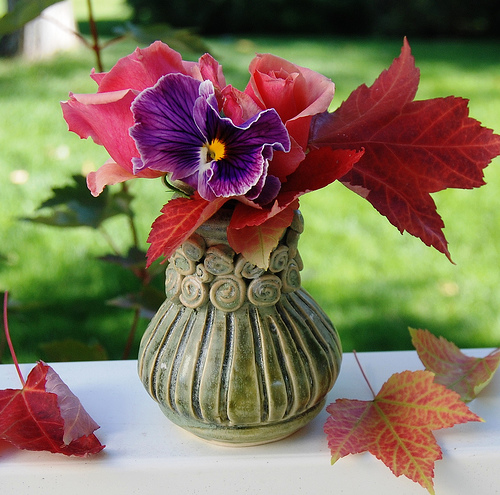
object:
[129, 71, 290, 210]
purple flower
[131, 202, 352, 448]
vase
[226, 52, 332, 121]
pink rose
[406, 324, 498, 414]
leaf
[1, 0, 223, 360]
plant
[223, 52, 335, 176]
rose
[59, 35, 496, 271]
flowers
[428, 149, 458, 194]
ground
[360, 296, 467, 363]
shadow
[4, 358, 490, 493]
table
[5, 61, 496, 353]
yard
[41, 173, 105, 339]
green leaves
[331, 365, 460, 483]
veins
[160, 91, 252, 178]
flower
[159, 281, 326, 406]
vase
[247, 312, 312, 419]
groove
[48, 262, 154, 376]
grass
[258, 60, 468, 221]
leaves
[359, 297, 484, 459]
leaves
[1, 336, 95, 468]
leaf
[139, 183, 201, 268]
leaves